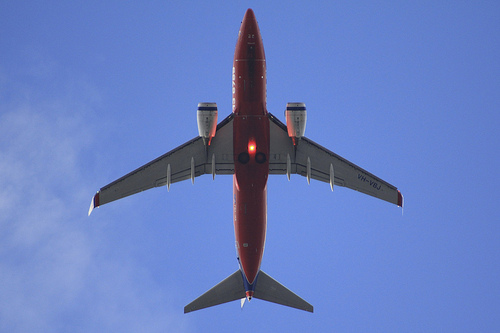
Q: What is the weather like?
A: It is clear.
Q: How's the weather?
A: It is clear.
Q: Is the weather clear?
A: Yes, it is clear.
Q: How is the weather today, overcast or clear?
A: It is clear.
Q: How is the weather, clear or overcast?
A: It is clear.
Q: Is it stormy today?
A: No, it is clear.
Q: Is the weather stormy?
A: No, it is clear.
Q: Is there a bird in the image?
A: No, there are no birds.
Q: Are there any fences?
A: No, there are no fences.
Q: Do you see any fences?
A: No, there are no fences.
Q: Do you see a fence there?
A: No, there are no fences.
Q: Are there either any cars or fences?
A: No, there are no fences or cars.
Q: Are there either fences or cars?
A: No, there are no fences or cars.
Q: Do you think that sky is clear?
A: Yes, the sky is clear.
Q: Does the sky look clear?
A: Yes, the sky is clear.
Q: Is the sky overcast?
A: No, the sky is clear.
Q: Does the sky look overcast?
A: No, the sky is clear.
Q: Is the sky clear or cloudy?
A: The sky is clear.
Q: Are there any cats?
A: No, there are no cats.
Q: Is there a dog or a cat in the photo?
A: No, there are no cats or dogs.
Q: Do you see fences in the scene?
A: No, there are no fences.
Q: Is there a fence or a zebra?
A: No, there are no fences or zebras.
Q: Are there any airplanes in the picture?
A: Yes, there is an airplane.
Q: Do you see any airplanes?
A: Yes, there is an airplane.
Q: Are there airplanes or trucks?
A: Yes, there is an airplane.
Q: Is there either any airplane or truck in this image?
A: Yes, there is an airplane.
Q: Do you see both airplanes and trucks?
A: No, there is an airplane but no trucks.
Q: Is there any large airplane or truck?
A: Yes, there is a large airplane.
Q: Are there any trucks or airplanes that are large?
A: Yes, the airplane is large.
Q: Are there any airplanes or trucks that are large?
A: Yes, the airplane is large.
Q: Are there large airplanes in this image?
A: Yes, there is a large airplane.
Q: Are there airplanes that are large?
A: Yes, there is an airplane that is large.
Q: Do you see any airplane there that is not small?
A: Yes, there is a large airplane.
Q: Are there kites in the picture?
A: No, there are no kites.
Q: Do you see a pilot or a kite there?
A: No, there are no kites or pilots.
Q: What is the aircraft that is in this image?
A: The aircraft is an airplane.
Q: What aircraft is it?
A: The aircraft is an airplane.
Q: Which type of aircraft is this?
A: This is an airplane.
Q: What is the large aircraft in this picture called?
A: The aircraft is an airplane.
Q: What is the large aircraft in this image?
A: The aircraft is an airplane.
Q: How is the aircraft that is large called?
A: The aircraft is an airplane.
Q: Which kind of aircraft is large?
A: The aircraft is an airplane.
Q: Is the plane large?
A: Yes, the plane is large.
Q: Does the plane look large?
A: Yes, the plane is large.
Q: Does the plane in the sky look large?
A: Yes, the plane is large.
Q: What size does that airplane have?
A: The airplane has large size.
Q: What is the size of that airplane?
A: The airplane is large.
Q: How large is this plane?
A: The plane is large.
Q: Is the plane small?
A: No, the plane is large.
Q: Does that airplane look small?
A: No, the airplane is large.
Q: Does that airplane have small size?
A: No, the airplane is large.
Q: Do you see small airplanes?
A: No, there is an airplane but it is large.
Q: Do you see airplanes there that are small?
A: No, there is an airplane but it is large.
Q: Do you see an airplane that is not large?
A: No, there is an airplane but it is large.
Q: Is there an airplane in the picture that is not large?
A: No, there is an airplane but it is large.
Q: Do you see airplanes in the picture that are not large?
A: No, there is an airplane but it is large.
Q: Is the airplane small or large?
A: The airplane is large.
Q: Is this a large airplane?
A: Yes, this is a large airplane.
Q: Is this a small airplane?
A: No, this is a large airplane.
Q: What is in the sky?
A: The plane is in the sky.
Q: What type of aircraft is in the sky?
A: The aircraft is an airplane.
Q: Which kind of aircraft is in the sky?
A: The aircraft is an airplane.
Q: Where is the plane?
A: The plane is in the sky.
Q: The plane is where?
A: The plane is in the sky.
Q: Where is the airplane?
A: The plane is in the sky.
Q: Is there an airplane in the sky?
A: Yes, there is an airplane in the sky.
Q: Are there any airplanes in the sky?
A: Yes, there is an airplane in the sky.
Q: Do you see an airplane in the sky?
A: Yes, there is an airplane in the sky.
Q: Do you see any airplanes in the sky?
A: Yes, there is an airplane in the sky.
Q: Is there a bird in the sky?
A: No, there is an airplane in the sky.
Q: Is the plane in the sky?
A: Yes, the plane is in the sky.